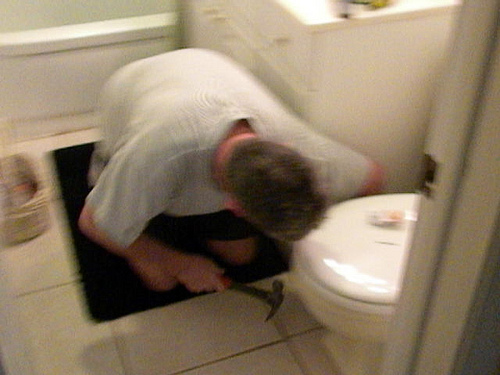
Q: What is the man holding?
A: A hammer.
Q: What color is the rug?
A: Black.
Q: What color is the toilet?
A: White.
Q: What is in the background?
A: A tub.